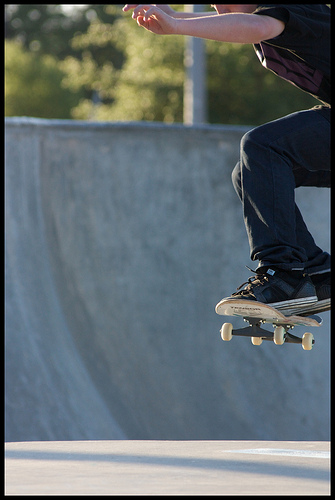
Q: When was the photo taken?
A: Daytime.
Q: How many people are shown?
A: One.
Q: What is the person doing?
A: Skateboarding.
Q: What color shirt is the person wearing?
A: Black.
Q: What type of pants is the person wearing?
A: Jeans.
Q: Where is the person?
A: In the air.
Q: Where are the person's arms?
A: Up.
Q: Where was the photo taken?
A: Skate park.